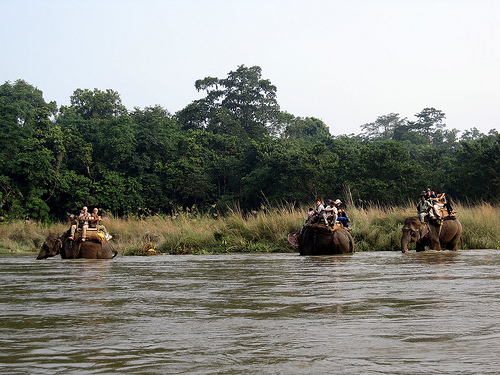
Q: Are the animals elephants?
A: Yes, all the animals are elephants.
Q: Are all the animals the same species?
A: Yes, all the animals are elephants.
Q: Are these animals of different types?
A: No, all the animals are elephants.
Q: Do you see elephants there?
A: Yes, there is an elephant.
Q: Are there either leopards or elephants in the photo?
A: Yes, there is an elephant.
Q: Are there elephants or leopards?
A: Yes, there is an elephant.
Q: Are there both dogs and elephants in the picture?
A: No, there is an elephant but no dogs.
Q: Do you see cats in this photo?
A: No, there are no cats.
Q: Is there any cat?
A: No, there are no cats.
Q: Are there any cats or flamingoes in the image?
A: No, there are no cats or flamingoes.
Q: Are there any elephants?
A: Yes, there is an elephant.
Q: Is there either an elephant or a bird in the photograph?
A: Yes, there is an elephant.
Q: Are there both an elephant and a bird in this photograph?
A: No, there is an elephant but no birds.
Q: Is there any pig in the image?
A: No, there are no pigs.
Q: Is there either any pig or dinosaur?
A: No, there are no pigs or dinosaurs.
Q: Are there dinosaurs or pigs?
A: No, there are no pigs or dinosaurs.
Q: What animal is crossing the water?
A: The elephant is crossing the water.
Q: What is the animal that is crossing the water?
A: The animal is an elephant.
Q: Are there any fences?
A: No, there are no fences.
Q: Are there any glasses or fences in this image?
A: No, there are no fences or glasses.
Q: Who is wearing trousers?
A: The man is wearing trousers.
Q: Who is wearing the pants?
A: The man is wearing trousers.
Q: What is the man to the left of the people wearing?
A: The man is wearing pants.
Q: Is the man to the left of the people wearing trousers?
A: Yes, the man is wearing trousers.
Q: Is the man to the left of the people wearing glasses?
A: No, the man is wearing trousers.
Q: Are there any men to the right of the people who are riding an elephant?
A: Yes, there is a man to the right of the people.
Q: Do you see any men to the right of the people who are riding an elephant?
A: Yes, there is a man to the right of the people.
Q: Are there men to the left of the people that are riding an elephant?
A: No, the man is to the right of the people.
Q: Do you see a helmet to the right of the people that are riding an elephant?
A: No, there is a man to the right of the people.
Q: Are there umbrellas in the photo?
A: No, there are no umbrellas.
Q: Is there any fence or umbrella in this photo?
A: No, there are no umbrellas or fences.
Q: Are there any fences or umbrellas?
A: No, there are no umbrellas or fences.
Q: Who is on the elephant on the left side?
A: The people are on the elephant.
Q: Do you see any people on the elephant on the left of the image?
A: Yes, there are people on the elephant.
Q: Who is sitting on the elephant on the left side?
A: The people are sitting on the elephant.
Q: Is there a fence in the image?
A: No, there are no fences.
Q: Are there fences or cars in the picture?
A: No, there are no fences or cars.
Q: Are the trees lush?
A: Yes, the trees are lush.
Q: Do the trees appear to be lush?
A: Yes, the trees are lush.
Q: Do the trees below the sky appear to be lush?
A: Yes, the trees are lush.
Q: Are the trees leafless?
A: No, the trees are lush.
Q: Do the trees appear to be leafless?
A: No, the trees are lush.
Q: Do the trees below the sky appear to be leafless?
A: No, the trees are lush.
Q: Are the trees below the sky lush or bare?
A: The trees are lush.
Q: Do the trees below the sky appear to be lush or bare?
A: The trees are lush.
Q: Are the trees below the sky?
A: Yes, the trees are below the sky.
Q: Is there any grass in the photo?
A: Yes, there is grass.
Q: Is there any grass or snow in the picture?
A: Yes, there is grass.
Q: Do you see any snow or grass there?
A: Yes, there is grass.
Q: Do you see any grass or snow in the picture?
A: Yes, there is grass.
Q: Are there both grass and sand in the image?
A: No, there is grass but no sand.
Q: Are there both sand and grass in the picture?
A: No, there is grass but no sand.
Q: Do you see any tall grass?
A: Yes, there is tall grass.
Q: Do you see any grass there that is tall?
A: Yes, there is grass that is tall.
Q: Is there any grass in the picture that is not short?
A: Yes, there is tall grass.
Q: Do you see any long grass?
A: Yes, there is long grass.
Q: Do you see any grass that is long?
A: Yes, there is long grass.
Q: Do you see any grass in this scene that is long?
A: Yes, there is grass that is long.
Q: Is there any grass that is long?
A: Yes, there is grass that is long.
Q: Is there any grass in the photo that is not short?
A: Yes, there is long grass.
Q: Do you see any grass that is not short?
A: Yes, there is long grass.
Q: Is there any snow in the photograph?
A: No, there is no snow.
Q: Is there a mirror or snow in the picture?
A: No, there are no snow or mirrors.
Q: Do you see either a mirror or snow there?
A: No, there are no snow or mirrors.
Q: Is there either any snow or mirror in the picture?
A: No, there are no snow or mirrors.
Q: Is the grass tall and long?
A: Yes, the grass is tall and long.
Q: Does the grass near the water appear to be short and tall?
A: No, the grass is tall but long.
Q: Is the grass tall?
A: Yes, the grass is tall.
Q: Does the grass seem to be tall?
A: Yes, the grass is tall.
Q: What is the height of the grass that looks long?
A: The grass is tall.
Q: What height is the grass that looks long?
A: The grass is tall.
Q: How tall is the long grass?
A: The grass is tall.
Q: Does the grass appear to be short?
A: No, the grass is tall.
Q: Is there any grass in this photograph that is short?
A: No, there is grass but it is tall.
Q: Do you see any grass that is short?
A: No, there is grass but it is tall.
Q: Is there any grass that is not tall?
A: No, there is grass but it is tall.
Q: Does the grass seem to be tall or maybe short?
A: The grass is tall.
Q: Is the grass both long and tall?
A: Yes, the grass is long and tall.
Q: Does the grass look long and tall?
A: Yes, the grass is long and tall.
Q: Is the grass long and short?
A: No, the grass is long but tall.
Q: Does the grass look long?
A: Yes, the grass is long.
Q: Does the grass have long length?
A: Yes, the grass is long.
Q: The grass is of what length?
A: The grass is long.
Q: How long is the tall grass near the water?
A: The grass is long.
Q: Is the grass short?
A: No, the grass is long.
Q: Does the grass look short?
A: No, the grass is long.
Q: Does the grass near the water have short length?
A: No, the grass is long.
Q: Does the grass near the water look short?
A: No, the grass is long.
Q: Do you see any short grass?
A: No, there is grass but it is long.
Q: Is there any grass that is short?
A: No, there is grass but it is long.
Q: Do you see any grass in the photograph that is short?
A: No, there is grass but it is long.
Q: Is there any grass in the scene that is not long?
A: No, there is grass but it is long.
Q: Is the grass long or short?
A: The grass is long.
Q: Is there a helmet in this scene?
A: No, there are no helmets.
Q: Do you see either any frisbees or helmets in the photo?
A: No, there are no helmets or frisbees.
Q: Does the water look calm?
A: Yes, the water is calm.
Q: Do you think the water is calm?
A: Yes, the water is calm.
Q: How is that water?
A: The water is calm.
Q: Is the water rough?
A: No, the water is calm.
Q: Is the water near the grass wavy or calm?
A: The water is calm.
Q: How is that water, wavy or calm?
A: The water is calm.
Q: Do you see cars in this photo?
A: No, there are no cars.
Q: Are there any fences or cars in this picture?
A: No, there are no cars or fences.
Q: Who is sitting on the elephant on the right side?
A: The people are sitting on the elephant.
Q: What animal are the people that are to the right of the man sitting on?
A: The people are sitting on the elephant.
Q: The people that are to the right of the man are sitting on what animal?
A: The people are sitting on the elephant.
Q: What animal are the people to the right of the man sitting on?
A: The people are sitting on the elephant.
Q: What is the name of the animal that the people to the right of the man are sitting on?
A: The animal is an elephant.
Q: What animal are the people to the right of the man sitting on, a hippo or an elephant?
A: The people are sitting on an elephant.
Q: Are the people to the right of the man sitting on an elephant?
A: Yes, the people are sitting on an elephant.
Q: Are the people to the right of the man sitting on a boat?
A: No, the people are sitting on an elephant.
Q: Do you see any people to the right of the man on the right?
A: Yes, there are people to the right of the man.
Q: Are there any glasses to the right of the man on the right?
A: No, there are people to the right of the man.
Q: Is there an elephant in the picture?
A: Yes, there is an elephant.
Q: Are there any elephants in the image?
A: Yes, there is an elephant.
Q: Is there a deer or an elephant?
A: Yes, there is an elephant.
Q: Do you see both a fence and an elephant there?
A: No, there is an elephant but no fences.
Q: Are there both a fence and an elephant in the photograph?
A: No, there is an elephant but no fences.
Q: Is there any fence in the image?
A: No, there are no fences.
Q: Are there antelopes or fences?
A: No, there are no fences or antelopes.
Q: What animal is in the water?
A: The elephant is in the water.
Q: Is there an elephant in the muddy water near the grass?
A: Yes, there is an elephant in the water.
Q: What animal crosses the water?
A: The elephant crosses the water.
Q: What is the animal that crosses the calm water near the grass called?
A: The animal is an elephant.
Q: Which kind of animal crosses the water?
A: The animal is an elephant.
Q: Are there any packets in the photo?
A: No, there are no packets.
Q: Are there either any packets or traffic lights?
A: No, there are no packets or traffic lights.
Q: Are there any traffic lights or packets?
A: No, there are no packets or traffic lights.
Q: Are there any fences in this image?
A: No, there are no fences.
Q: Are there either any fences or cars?
A: No, there are no fences or cars.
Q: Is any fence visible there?
A: No, there are no fences.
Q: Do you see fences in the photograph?
A: No, there are no fences.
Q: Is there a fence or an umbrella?
A: No, there are no fences or umbrellas.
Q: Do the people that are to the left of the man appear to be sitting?
A: Yes, the people are sitting.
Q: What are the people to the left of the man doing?
A: The people are sitting.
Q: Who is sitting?
A: The people are sitting.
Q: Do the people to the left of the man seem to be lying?
A: No, the people are sitting.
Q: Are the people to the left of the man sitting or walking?
A: The people are sitting.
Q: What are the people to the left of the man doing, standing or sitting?
A: The people are sitting.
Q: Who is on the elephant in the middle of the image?
A: The people are on the elephant.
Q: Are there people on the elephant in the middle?
A: Yes, there are people on the elephant.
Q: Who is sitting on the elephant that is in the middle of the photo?
A: The people are sitting on the elephant.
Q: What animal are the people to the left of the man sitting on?
A: The people are sitting on the elephant.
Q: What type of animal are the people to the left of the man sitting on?
A: The people are sitting on the elephant.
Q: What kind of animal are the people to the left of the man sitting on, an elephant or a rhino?
A: The people are sitting on an elephant.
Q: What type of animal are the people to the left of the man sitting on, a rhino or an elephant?
A: The people are sitting on an elephant.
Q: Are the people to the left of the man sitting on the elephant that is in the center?
A: Yes, the people are sitting on the elephant.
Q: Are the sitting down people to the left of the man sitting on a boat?
A: No, the people are sitting on the elephant.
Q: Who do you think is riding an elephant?
A: The people are riding an elephant.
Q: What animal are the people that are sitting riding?
A: The people are riding an elephant.